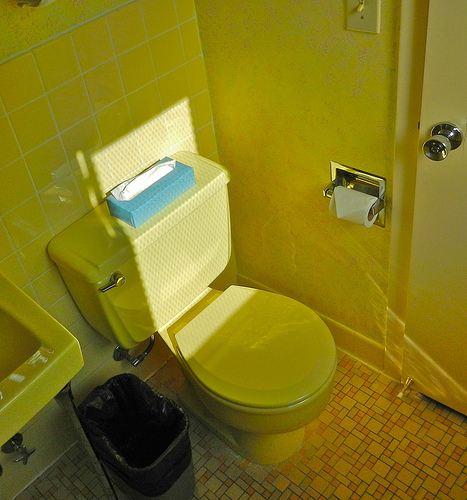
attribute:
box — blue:
[94, 154, 198, 232]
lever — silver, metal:
[94, 268, 127, 297]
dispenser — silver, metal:
[312, 155, 390, 236]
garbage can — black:
[73, 371, 202, 499]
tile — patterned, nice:
[9, 348, 463, 498]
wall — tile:
[1, 2, 241, 499]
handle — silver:
[418, 112, 465, 172]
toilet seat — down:
[172, 278, 341, 412]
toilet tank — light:
[43, 146, 236, 357]